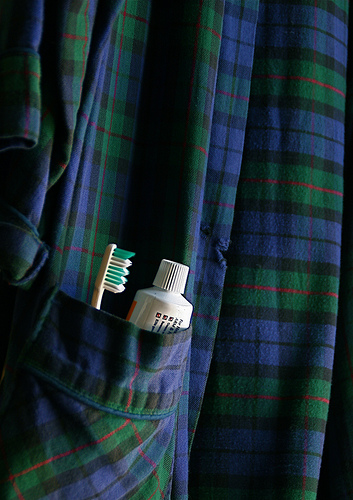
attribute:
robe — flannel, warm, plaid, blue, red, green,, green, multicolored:
[2, 4, 347, 494]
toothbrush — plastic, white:
[86, 239, 134, 317]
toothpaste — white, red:
[130, 255, 199, 331]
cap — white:
[154, 257, 190, 296]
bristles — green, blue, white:
[112, 244, 134, 297]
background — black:
[314, 6, 352, 498]